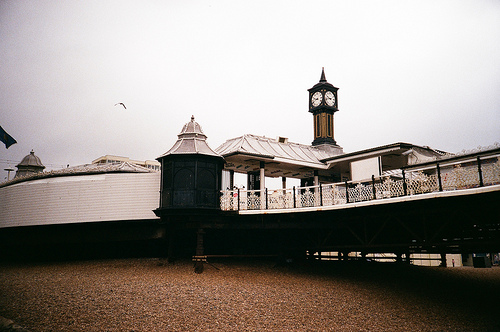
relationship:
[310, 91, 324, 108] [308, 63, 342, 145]
clock on tower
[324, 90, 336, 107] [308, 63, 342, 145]
clock on tower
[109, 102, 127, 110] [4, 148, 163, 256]
bird over pavillion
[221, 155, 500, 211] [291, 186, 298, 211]
fence has post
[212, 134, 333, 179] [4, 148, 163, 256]
roof near pavillion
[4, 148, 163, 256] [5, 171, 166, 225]
pavillion behind wall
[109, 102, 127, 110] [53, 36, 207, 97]
bird in sky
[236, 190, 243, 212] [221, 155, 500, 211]
pole on fence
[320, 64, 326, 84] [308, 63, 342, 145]
tip of tower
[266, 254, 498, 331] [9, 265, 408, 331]
shadow on ground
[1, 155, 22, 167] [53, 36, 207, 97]
powerlines in sky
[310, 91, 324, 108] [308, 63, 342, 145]
clock in tower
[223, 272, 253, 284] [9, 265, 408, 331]
gravel on ground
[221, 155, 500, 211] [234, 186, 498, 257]
fence on bridge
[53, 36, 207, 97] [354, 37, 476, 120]
sky has clouds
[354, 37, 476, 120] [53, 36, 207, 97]
clouds in sky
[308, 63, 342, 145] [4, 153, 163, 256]
tower near pavillion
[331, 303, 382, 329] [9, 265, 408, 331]
sand on ground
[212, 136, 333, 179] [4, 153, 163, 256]
roof on pavillion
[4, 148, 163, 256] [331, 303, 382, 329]
pavillion above sand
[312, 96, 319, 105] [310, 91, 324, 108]
hands on clock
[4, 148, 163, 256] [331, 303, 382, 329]
pavillion over sand